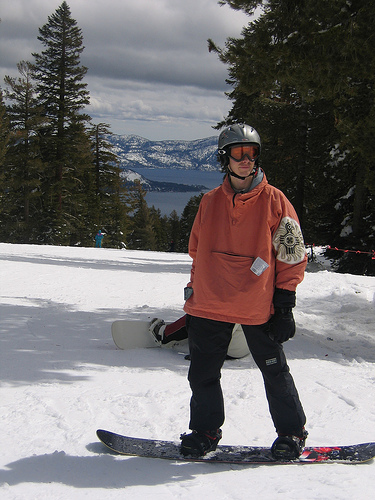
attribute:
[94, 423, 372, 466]
snowboard — black, red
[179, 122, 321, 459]
man — standing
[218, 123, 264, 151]
helmet — silver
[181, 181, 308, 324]
jacket — orange, ski jacket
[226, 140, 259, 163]
goggles — pair, amber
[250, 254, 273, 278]
ticket — ski lift pass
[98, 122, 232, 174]
mountains — snow covered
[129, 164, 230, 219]
lake — blue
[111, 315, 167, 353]
snowboard — white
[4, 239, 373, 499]
snow — white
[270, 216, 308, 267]
graphic — eagle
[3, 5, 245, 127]
clouds — gray, white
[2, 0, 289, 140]
sky — cloudy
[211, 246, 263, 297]
pocket — kangaroo pocket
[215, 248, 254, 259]
zipper — horizontal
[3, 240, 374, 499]
ground — snow covered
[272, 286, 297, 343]
glove — black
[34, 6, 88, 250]
tree — green, large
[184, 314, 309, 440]
pants — black